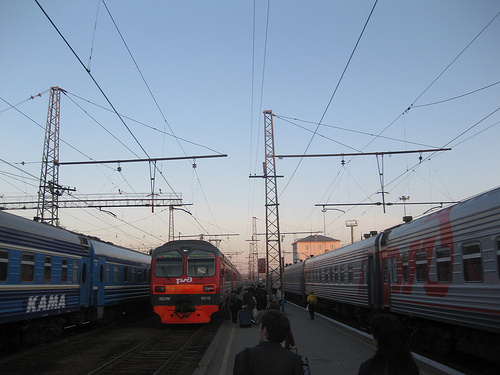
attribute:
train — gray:
[259, 182, 498, 342]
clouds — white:
[55, 200, 395, 277]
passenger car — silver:
[374, 182, 499, 337]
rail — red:
[159, 217, 327, 344]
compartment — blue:
[3, 247, 88, 315]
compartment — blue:
[91, 256, 126, 305]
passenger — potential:
[302, 288, 322, 319]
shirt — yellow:
[303, 293, 322, 304]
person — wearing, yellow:
[306, 290, 320, 319]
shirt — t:
[305, 294, 318, 300]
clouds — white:
[73, 202, 416, 275]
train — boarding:
[113, 203, 302, 365]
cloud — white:
[318, 203, 410, 248]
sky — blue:
[4, 0, 494, 272]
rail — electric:
[253, 110, 344, 371]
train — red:
[152, 237, 243, 324]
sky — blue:
[424, 24, 477, 55]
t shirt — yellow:
[306, 290, 316, 300]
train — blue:
[0, 212, 151, 349]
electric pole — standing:
[259, 107, 289, 309]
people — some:
[222, 270, 410, 372]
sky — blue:
[0, 0, 498, 188]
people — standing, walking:
[226, 278, 318, 373]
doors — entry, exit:
[77, 257, 110, 315]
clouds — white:
[312, 93, 494, 184]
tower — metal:
[247, 88, 291, 321]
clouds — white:
[30, 135, 471, 254]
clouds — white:
[254, 78, 378, 179]